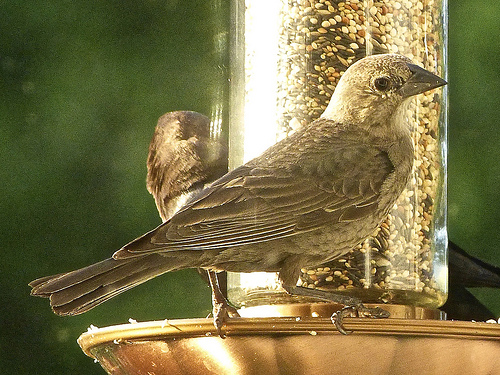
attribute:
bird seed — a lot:
[221, 10, 459, 297]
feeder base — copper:
[76, 315, 498, 372]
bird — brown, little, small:
[26, 51, 449, 338]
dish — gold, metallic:
[75, 314, 498, 373]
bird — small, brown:
[142, 109, 498, 319]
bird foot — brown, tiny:
[329, 298, 388, 338]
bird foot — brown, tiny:
[207, 301, 242, 340]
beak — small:
[398, 63, 449, 99]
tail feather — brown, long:
[17, 246, 185, 322]